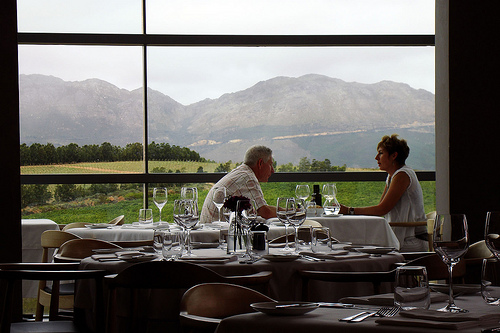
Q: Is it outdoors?
A: Yes, it is outdoors.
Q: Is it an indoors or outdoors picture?
A: It is outdoors.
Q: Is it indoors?
A: No, it is outdoors.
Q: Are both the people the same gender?
A: No, they are both male and female.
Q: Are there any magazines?
A: No, there are no magazines.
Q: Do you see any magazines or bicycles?
A: No, there are no magazines or bicycles.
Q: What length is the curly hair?
A: The hair is short.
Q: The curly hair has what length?
A: The hair is short.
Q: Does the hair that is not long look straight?
A: No, the hair is curly.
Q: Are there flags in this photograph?
A: No, there are no flags.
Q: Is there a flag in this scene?
A: No, there are no flags.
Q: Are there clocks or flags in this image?
A: No, there are no flags or clocks.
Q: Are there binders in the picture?
A: No, there are no binders.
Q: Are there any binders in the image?
A: No, there are no binders.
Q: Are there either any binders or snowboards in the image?
A: No, there are no binders or snowboards.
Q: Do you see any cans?
A: No, there are no cans.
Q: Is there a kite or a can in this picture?
A: No, there are no cans or kites.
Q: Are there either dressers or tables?
A: Yes, there is a table.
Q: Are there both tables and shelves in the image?
A: No, there is a table but no shelves.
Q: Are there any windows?
A: Yes, there is a window.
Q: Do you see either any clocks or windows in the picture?
A: Yes, there is a window.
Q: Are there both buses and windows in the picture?
A: No, there is a window but no buses.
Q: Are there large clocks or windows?
A: Yes, there is a large window.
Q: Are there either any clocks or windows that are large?
A: Yes, the window is large.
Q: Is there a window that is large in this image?
A: Yes, there is a large window.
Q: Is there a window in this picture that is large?
A: Yes, there is a window that is large.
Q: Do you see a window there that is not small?
A: Yes, there is a large window.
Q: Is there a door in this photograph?
A: No, there are no doors.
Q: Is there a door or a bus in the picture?
A: No, there are no doors or buses.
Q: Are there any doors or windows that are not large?
A: No, there is a window but it is large.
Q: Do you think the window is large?
A: Yes, the window is large.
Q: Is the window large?
A: Yes, the window is large.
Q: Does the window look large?
A: Yes, the window is large.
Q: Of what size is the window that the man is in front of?
A: The window is large.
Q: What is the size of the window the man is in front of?
A: The window is large.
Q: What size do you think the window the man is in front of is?
A: The window is large.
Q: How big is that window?
A: The window is large.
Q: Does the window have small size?
A: No, the window is large.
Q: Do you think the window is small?
A: No, the window is large.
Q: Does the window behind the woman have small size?
A: No, the window is large.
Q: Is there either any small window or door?
A: No, there is a window but it is large.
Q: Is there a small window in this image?
A: No, there is a window but it is large.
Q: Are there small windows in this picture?
A: No, there is a window but it is large.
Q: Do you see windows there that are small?
A: No, there is a window but it is large.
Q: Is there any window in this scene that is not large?
A: No, there is a window but it is large.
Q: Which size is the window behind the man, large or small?
A: The window is large.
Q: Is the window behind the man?
A: Yes, the window is behind the man.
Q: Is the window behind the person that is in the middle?
A: Yes, the window is behind the man.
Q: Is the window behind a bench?
A: No, the window is behind the man.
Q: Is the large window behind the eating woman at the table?
A: Yes, the window is behind the woman.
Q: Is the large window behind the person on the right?
A: Yes, the window is behind the woman.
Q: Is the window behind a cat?
A: No, the window is behind the woman.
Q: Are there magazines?
A: No, there are no magazines.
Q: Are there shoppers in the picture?
A: No, there are no shoppers.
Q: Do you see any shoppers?
A: No, there are no shoppers.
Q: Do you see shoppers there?
A: No, there are no shoppers.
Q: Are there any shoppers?
A: No, there are no shoppers.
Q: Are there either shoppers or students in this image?
A: No, there are no shoppers or students.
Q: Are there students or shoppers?
A: No, there are no shoppers or students.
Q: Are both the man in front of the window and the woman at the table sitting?
A: Yes, both the man and the woman are sitting.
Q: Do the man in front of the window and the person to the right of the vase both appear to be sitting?
A: Yes, both the man and the woman are sitting.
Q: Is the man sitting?
A: Yes, the man is sitting.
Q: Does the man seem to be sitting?
A: Yes, the man is sitting.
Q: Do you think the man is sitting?
A: Yes, the man is sitting.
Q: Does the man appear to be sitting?
A: Yes, the man is sitting.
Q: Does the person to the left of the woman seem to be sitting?
A: Yes, the man is sitting.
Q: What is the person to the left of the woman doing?
A: The man is sitting.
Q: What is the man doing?
A: The man is sitting.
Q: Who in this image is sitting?
A: The man is sitting.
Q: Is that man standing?
A: No, the man is sitting.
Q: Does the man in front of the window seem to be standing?
A: No, the man is sitting.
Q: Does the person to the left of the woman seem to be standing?
A: No, the man is sitting.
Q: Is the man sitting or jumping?
A: The man is sitting.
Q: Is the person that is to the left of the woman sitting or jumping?
A: The man is sitting.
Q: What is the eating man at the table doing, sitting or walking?
A: The man is sitting.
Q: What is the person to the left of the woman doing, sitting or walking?
A: The man is sitting.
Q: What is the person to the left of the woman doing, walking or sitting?
A: The man is sitting.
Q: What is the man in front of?
A: The man is in front of the window.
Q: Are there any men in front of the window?
A: Yes, there is a man in front of the window.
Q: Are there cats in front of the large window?
A: No, there is a man in front of the window.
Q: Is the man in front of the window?
A: Yes, the man is in front of the window.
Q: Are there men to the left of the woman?
A: Yes, there is a man to the left of the woman.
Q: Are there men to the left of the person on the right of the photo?
A: Yes, there is a man to the left of the woman.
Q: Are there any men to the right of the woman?
A: No, the man is to the left of the woman.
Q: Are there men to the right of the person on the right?
A: No, the man is to the left of the woman.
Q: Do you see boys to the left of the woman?
A: No, there is a man to the left of the woman.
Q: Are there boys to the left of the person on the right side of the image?
A: No, there is a man to the left of the woman.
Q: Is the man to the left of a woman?
A: Yes, the man is to the left of a woman.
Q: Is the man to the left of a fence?
A: No, the man is to the left of a woman.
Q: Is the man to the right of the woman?
A: No, the man is to the left of the woman.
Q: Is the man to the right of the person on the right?
A: No, the man is to the left of the woman.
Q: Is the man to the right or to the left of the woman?
A: The man is to the left of the woman.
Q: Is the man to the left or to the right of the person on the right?
A: The man is to the left of the woman.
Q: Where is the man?
A: The man is at the table.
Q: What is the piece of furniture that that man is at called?
A: The piece of furniture is a table.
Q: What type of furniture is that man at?
A: The man is at the table.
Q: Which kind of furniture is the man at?
A: The man is at the table.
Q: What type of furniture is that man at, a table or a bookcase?
A: The man is at a table.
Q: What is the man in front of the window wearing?
A: The man is wearing a shirt.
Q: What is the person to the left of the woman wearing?
A: The man is wearing a shirt.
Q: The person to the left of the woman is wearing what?
A: The man is wearing a shirt.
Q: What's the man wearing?
A: The man is wearing a shirt.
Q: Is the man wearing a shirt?
A: Yes, the man is wearing a shirt.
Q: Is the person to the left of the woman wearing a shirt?
A: Yes, the man is wearing a shirt.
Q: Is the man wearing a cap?
A: No, the man is wearing a shirt.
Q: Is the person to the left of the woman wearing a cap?
A: No, the man is wearing a shirt.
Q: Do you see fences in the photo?
A: No, there are no fences.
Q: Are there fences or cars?
A: No, there are no fences or cars.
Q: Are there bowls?
A: No, there are no bowls.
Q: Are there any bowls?
A: No, there are no bowls.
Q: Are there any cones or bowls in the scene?
A: No, there are no bowls or cones.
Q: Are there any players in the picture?
A: No, there are no players.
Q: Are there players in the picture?
A: No, there are no players.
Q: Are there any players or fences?
A: No, there are no players or fences.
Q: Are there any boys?
A: No, there are no boys.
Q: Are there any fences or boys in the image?
A: No, there are no boys or fences.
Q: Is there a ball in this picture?
A: No, there are no balls.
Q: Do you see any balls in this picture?
A: No, there are no balls.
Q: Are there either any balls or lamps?
A: No, there are no balls or lamps.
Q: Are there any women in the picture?
A: Yes, there is a woman.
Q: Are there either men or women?
A: Yes, there is a woman.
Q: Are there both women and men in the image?
A: Yes, there are both a woman and a man.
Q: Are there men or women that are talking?
A: Yes, the woman is talking.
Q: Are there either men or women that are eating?
A: Yes, the woman is eating.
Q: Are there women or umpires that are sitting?
A: Yes, the woman is sitting.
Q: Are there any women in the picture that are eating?
A: Yes, there is a woman that is eating.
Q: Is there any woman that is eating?
A: Yes, there is a woman that is eating.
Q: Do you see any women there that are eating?
A: Yes, there is a woman that is eating.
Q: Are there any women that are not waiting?
A: Yes, there is a woman that is eating.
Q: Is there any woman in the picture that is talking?
A: Yes, there is a woman that is talking.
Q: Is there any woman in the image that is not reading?
A: Yes, there is a woman that is talking.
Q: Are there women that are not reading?
A: Yes, there is a woman that is talking.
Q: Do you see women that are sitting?
A: Yes, there is a woman that is sitting.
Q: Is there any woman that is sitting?
A: Yes, there is a woman that is sitting.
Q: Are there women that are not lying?
A: Yes, there is a woman that is sitting.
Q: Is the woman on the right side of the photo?
A: Yes, the woman is on the right of the image.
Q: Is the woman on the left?
A: No, the woman is on the right of the image.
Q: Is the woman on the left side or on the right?
A: The woman is on the right of the image.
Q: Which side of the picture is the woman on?
A: The woman is on the right of the image.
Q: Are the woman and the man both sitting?
A: Yes, both the woman and the man are sitting.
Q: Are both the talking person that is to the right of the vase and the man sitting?
A: Yes, both the woman and the man are sitting.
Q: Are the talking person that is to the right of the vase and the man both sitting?
A: Yes, both the woman and the man are sitting.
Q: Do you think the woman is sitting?
A: Yes, the woman is sitting.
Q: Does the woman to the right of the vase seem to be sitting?
A: Yes, the woman is sitting.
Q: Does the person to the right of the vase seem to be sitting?
A: Yes, the woman is sitting.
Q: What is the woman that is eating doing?
A: The woman is sitting.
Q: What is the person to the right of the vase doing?
A: The woman is sitting.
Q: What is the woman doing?
A: The woman is sitting.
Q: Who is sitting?
A: The woman is sitting.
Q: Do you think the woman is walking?
A: No, the woman is sitting.